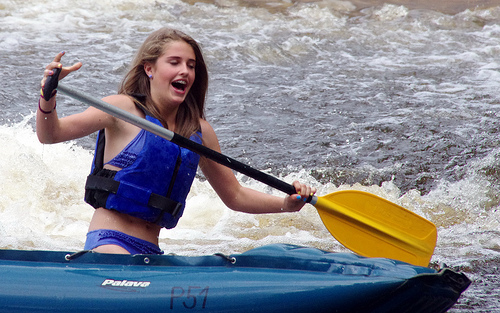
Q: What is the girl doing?
A: Paddling.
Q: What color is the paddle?
A: Yellow.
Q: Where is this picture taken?
A: A river.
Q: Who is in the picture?
A: A girl.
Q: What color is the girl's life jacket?
A: Blue.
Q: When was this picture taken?
A: Daytime.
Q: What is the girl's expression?
A: Excitement.